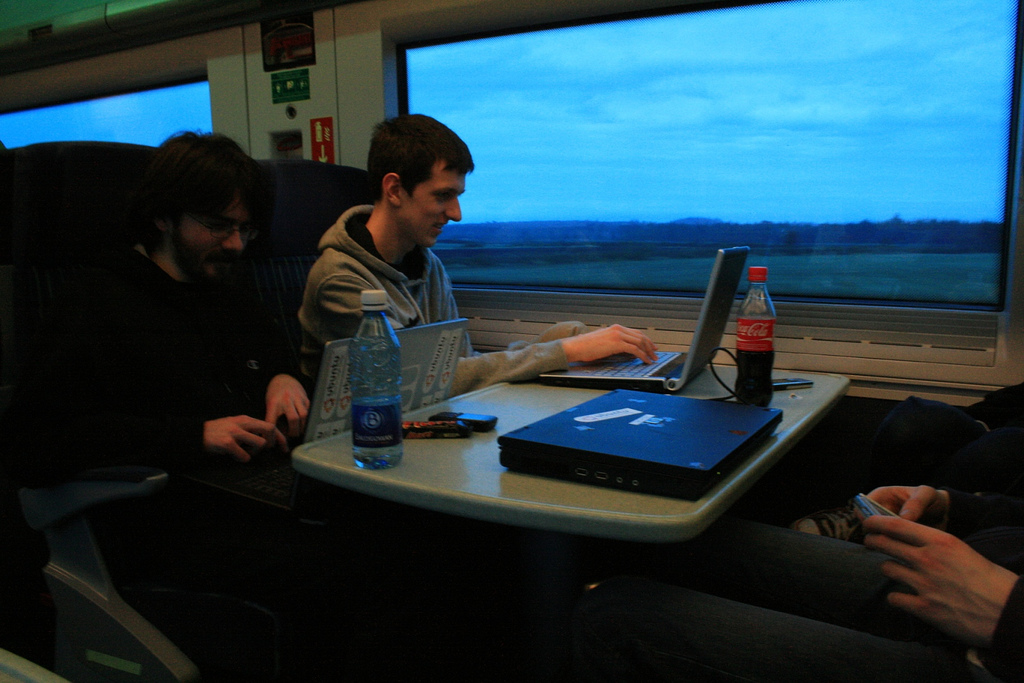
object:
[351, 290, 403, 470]
bottle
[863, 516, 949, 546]
finger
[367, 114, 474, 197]
hair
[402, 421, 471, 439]
cell phone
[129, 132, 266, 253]
hair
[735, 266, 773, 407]
bottle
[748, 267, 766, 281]
lid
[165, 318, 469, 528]
lap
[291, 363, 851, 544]
table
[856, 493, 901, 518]
cell phone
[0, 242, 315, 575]
sweatshirt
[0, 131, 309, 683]
man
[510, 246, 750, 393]
laptop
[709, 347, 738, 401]
cords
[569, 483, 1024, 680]
man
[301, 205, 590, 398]
sweatshirt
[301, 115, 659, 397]
man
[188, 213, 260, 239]
glasses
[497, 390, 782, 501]
computer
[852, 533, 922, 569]
finger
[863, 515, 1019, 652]
hand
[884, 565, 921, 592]
finger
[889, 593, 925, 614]
finger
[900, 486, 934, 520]
finger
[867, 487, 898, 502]
finger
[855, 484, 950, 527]
hand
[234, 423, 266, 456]
finger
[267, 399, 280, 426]
finger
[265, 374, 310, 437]
hand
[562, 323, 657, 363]
hand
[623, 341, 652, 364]
finger